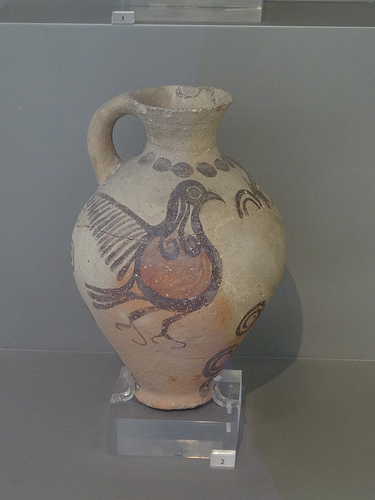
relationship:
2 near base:
[218, 458, 227, 466] [110, 363, 242, 461]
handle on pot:
[87, 92, 145, 187] [70, 86, 288, 410]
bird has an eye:
[81, 179, 227, 350] [185, 185, 203, 199]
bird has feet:
[81, 179, 227, 350] [114, 319, 187, 350]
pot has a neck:
[70, 86, 288, 410] [129, 112, 234, 157]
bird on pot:
[81, 179, 227, 350] [70, 86, 288, 410]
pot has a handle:
[70, 86, 288, 410] [87, 92, 145, 187]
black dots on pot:
[138, 152, 237, 177] [70, 86, 288, 410]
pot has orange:
[70, 86, 288, 410] [83, 226, 248, 411]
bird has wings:
[81, 179, 227, 350] [84, 192, 156, 280]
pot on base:
[70, 86, 288, 410] [110, 363, 242, 461]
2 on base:
[218, 458, 227, 466] [110, 363, 242, 461]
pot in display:
[70, 86, 288, 410] [0, 22, 373, 499]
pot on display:
[70, 86, 288, 410] [0, 22, 373, 499]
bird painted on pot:
[81, 179, 227, 350] [70, 86, 288, 410]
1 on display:
[121, 14, 126, 22] [0, 22, 373, 499]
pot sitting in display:
[70, 86, 288, 410] [0, 22, 373, 499]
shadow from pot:
[221, 265, 303, 396] [70, 86, 288, 410]